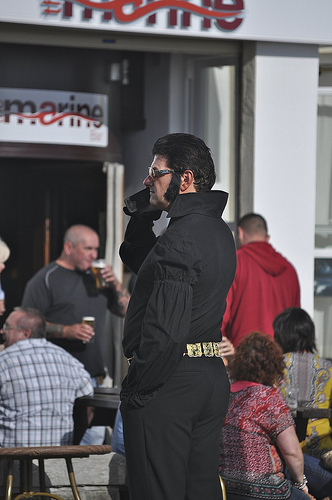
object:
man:
[110, 126, 242, 497]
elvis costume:
[110, 130, 235, 499]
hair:
[151, 130, 217, 203]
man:
[20, 219, 131, 447]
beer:
[88, 257, 113, 291]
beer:
[79, 315, 97, 344]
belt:
[126, 339, 224, 367]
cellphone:
[122, 186, 157, 215]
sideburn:
[162, 167, 185, 205]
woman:
[218, 331, 316, 499]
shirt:
[219, 380, 297, 498]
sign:
[34, 0, 248, 39]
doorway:
[1, 21, 261, 499]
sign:
[0, 87, 112, 137]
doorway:
[0, 146, 125, 500]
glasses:
[145, 160, 179, 181]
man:
[0, 304, 95, 455]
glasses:
[1, 319, 28, 333]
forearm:
[104, 279, 129, 318]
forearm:
[37, 318, 67, 340]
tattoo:
[114, 285, 122, 297]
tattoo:
[110, 301, 123, 315]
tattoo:
[123, 289, 133, 303]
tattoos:
[43, 322, 68, 338]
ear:
[179, 165, 195, 192]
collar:
[166, 187, 231, 221]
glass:
[89, 258, 111, 293]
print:
[219, 379, 293, 498]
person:
[269, 305, 332, 467]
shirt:
[270, 350, 331, 459]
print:
[278, 350, 332, 457]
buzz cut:
[234, 212, 271, 240]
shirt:
[0, 337, 95, 450]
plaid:
[7, 352, 71, 439]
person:
[221, 209, 303, 397]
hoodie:
[221, 242, 302, 352]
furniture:
[0, 438, 116, 500]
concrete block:
[0, 450, 128, 499]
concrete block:
[2, 483, 123, 498]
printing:
[39, 1, 243, 35]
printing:
[0, 94, 105, 130]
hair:
[226, 329, 289, 389]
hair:
[12, 304, 47, 340]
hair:
[271, 304, 319, 355]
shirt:
[112, 187, 239, 403]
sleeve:
[118, 221, 198, 413]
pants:
[120, 353, 232, 500]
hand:
[98, 265, 119, 290]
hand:
[66, 322, 97, 345]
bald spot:
[64, 223, 100, 244]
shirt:
[18, 257, 111, 377]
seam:
[41, 265, 61, 288]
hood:
[239, 240, 291, 278]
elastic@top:
[151, 277, 192, 289]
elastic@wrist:
[120, 378, 150, 401]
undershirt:
[229, 380, 263, 393]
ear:
[236, 224, 244, 243]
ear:
[264, 232, 271, 243]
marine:
[6, 95, 105, 130]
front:
[151, 132, 187, 155]